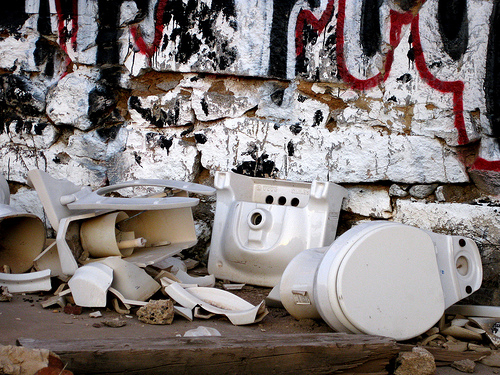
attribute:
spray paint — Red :
[376, 4, 428, 94]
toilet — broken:
[33, 159, 223, 329]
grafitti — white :
[0, 0, 500, 179]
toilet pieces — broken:
[1, 167, 483, 339]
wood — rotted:
[218, 300, 348, 372]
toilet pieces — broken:
[68, 259, 160, 309]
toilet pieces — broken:
[145, 258, 268, 326]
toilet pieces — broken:
[206, 168, 346, 283]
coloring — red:
[404, 10, 429, 67]